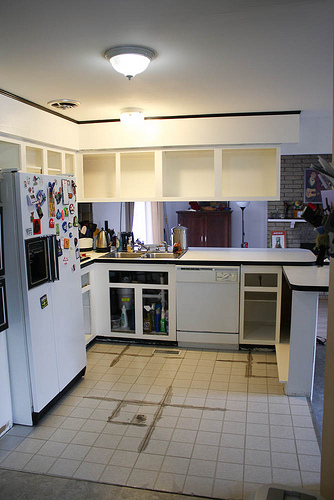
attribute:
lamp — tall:
[95, 47, 154, 82]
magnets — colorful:
[30, 186, 79, 238]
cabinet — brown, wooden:
[81, 153, 275, 200]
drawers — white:
[106, 270, 170, 284]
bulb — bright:
[109, 53, 149, 76]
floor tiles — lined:
[102, 390, 272, 464]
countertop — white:
[79, 237, 320, 269]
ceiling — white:
[39, 10, 322, 129]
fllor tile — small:
[170, 424, 205, 450]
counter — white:
[179, 240, 320, 260]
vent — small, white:
[151, 345, 184, 356]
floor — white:
[4, 337, 326, 493]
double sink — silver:
[102, 249, 177, 265]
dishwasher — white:
[171, 261, 241, 354]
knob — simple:
[221, 270, 232, 282]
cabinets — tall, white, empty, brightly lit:
[73, 147, 285, 197]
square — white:
[163, 143, 229, 192]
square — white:
[80, 150, 188, 189]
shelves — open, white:
[7, 138, 295, 200]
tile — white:
[142, 358, 165, 371]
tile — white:
[188, 377, 211, 389]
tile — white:
[168, 426, 199, 444]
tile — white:
[88, 407, 117, 420]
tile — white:
[97, 370, 122, 381]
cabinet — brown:
[175, 208, 232, 243]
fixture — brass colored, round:
[106, 45, 156, 77]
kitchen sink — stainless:
[105, 249, 183, 267]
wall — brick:
[272, 150, 328, 252]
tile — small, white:
[14, 344, 284, 498]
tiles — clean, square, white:
[203, 433, 276, 467]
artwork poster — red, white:
[266, 225, 292, 251]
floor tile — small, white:
[125, 352, 242, 431]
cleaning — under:
[115, 283, 168, 328]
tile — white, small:
[98, 351, 278, 479]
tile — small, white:
[121, 366, 143, 376]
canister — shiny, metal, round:
[161, 214, 197, 260]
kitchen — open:
[1, 42, 326, 498]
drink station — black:
[26, 236, 60, 289]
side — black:
[92, 258, 314, 266]